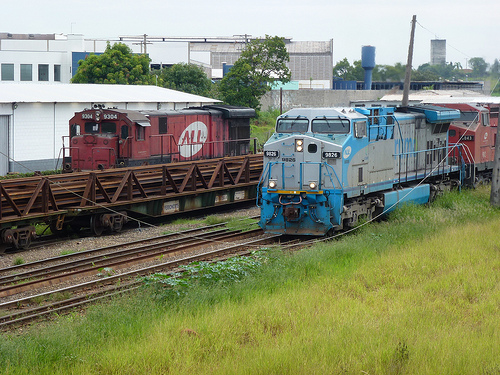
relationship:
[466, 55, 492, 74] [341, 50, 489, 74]
tree on horizon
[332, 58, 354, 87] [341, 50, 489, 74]
tree on horizon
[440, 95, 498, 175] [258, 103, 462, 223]
red engine behind engine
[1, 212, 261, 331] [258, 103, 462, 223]
tracks ahead of engine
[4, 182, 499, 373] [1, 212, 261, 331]
grass next to tracks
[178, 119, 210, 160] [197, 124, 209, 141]
circle of white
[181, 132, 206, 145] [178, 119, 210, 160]
red letters on circle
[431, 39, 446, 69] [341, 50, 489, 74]
silo on horizon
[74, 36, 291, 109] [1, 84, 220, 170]
trees behind building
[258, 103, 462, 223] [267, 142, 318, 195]
engine has headlights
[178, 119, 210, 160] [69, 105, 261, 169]
logo on train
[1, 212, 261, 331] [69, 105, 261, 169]
tracks for engine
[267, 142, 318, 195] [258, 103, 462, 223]
headlights on engine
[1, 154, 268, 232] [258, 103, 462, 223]
platform by engine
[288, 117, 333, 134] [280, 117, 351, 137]
wipers on windshield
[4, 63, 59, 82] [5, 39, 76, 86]
windows on building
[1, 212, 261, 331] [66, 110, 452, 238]
tracks for two trains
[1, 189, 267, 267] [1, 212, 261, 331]
gravel on tracks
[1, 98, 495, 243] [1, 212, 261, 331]
wire over tracks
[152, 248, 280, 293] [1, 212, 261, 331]
bush alongside track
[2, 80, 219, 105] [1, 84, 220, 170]
roof on building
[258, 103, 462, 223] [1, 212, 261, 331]
engine on tracks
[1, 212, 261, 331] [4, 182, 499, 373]
tracks along side grass